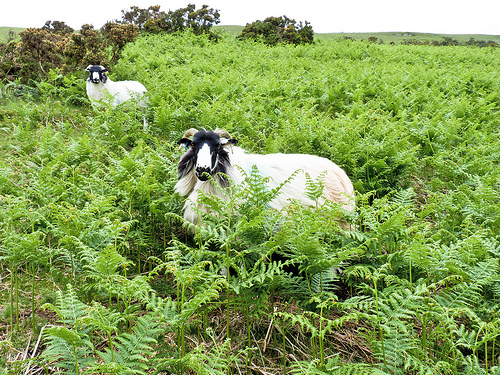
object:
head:
[172, 125, 238, 195]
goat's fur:
[241, 151, 326, 191]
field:
[273, 0, 499, 182]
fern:
[109, 161, 140, 191]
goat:
[82, 62, 151, 117]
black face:
[85, 65, 103, 83]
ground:
[443, 121, 454, 133]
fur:
[173, 127, 356, 230]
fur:
[81, 63, 148, 113]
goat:
[162, 121, 362, 281]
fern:
[409, 234, 466, 279]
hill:
[319, 29, 495, 39]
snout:
[193, 164, 213, 181]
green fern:
[123, 257, 171, 303]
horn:
[101, 64, 113, 71]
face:
[187, 130, 222, 182]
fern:
[440, 229, 487, 270]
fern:
[439, 314, 476, 355]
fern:
[227, 251, 304, 294]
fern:
[50, 281, 90, 331]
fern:
[197, 337, 237, 372]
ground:
[5, 343, 37, 360]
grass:
[410, 26, 498, 108]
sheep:
[173, 127, 355, 232]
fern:
[407, 188, 467, 240]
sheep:
[82, 63, 151, 134]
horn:
[181, 128, 198, 138]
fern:
[421, 35, 496, 66]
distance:
[3, 1, 496, 121]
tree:
[110, 4, 226, 43]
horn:
[84, 63, 93, 71]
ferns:
[2, 186, 131, 257]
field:
[149, 117, 500, 375]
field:
[3, 182, 317, 366]